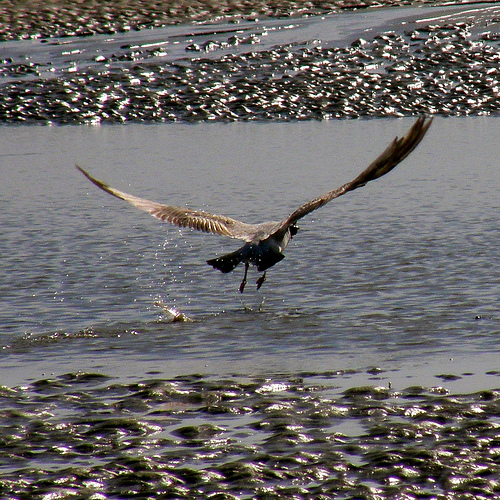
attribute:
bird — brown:
[106, 127, 448, 312]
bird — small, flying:
[72, 116, 438, 292]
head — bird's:
[286, 216, 300, 235]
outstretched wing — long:
[75, 162, 254, 244]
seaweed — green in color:
[218, 451, 282, 488]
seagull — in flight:
[74, 112, 433, 290]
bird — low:
[102, 116, 489, 320]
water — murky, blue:
[372, 208, 483, 349]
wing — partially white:
[124, 176, 211, 260]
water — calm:
[0, 121, 499, 383]